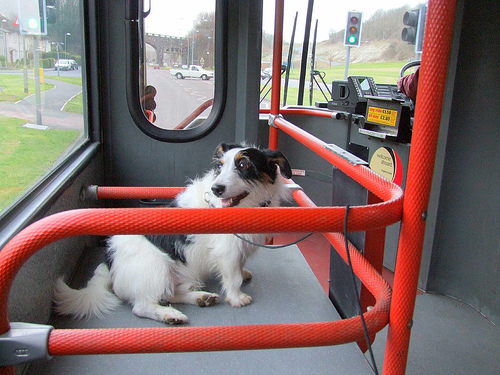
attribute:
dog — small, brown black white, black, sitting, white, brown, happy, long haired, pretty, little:
[51, 137, 303, 321]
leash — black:
[203, 196, 379, 374]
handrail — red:
[3, 114, 404, 359]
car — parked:
[53, 57, 71, 70]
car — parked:
[68, 59, 80, 70]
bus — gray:
[4, 4, 499, 373]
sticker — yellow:
[368, 105, 403, 127]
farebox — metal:
[330, 72, 409, 141]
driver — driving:
[396, 59, 420, 105]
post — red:
[387, 1, 465, 374]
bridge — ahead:
[145, 32, 208, 69]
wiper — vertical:
[283, 9, 300, 107]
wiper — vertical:
[307, 17, 321, 107]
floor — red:
[269, 210, 426, 323]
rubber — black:
[123, 3, 233, 142]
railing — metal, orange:
[173, 100, 216, 132]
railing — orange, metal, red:
[258, 104, 332, 120]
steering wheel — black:
[399, 57, 421, 88]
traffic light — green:
[341, 8, 365, 79]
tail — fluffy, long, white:
[49, 256, 126, 320]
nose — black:
[210, 183, 228, 198]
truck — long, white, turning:
[168, 60, 215, 82]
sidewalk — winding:
[11, 66, 90, 132]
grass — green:
[2, 67, 89, 206]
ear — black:
[262, 147, 294, 181]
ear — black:
[212, 140, 242, 156]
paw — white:
[227, 290, 257, 313]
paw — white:
[161, 307, 190, 326]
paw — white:
[239, 268, 258, 281]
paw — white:
[195, 291, 224, 310]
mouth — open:
[219, 193, 252, 208]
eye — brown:
[238, 161, 247, 169]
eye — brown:
[218, 161, 224, 170]